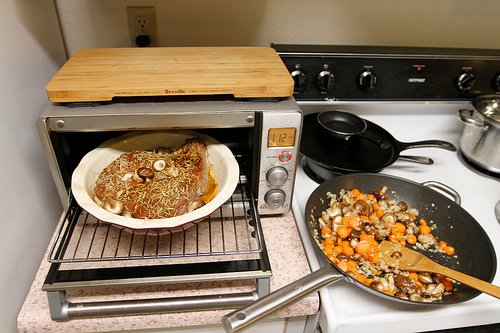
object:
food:
[308, 186, 464, 304]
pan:
[219, 173, 496, 333]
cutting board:
[45, 46, 294, 105]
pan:
[299, 110, 457, 185]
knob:
[357, 70, 378, 91]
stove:
[271, 43, 499, 333]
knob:
[315, 64, 335, 95]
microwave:
[29, 96, 304, 321]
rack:
[47, 144, 264, 264]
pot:
[457, 90, 500, 179]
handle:
[456, 108, 489, 131]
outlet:
[127, 2, 160, 49]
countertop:
[15, 190, 320, 333]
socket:
[125, 6, 160, 49]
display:
[267, 127, 297, 148]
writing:
[363, 65, 373, 71]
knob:
[457, 71, 478, 94]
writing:
[462, 67, 472, 72]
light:
[417, 66, 421, 71]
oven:
[36, 45, 303, 323]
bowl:
[71, 129, 240, 235]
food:
[93, 136, 218, 220]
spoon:
[374, 237, 500, 299]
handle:
[45, 278, 273, 323]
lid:
[470, 92, 500, 125]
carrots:
[355, 232, 380, 264]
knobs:
[264, 166, 288, 208]